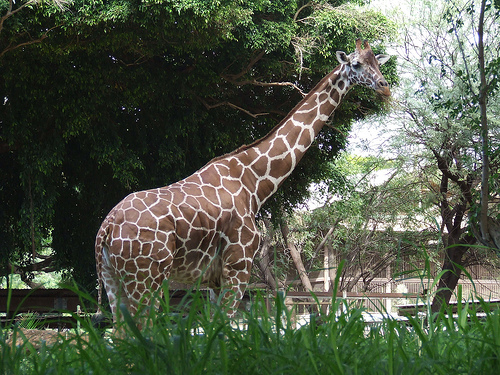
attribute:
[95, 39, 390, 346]
giraffe — tall, standing, brown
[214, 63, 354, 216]
neck — long, very long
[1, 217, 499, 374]
grass — overgrown, green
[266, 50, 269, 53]
leaf — green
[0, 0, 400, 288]
tree — tall, full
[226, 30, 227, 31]
leaf — green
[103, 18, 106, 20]
leaf — green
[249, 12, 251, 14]
leaf — green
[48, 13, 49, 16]
leaf — green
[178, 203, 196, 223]
patch — brown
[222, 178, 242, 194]
patch — brown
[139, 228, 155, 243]
patch — brown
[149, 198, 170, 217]
patch — brown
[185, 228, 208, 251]
patch — brown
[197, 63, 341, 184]
mane — short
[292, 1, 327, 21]
branch — brown, hanging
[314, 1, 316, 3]
leaf — green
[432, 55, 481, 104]
branch — brown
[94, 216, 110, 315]
tail — short, long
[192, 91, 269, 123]
branch — brown, hanging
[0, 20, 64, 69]
branch — brown, hanging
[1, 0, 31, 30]
branch — brown, hanging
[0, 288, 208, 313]
wall — brown, wood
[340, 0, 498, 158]
sky — cloudy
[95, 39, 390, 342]
skin — beautiful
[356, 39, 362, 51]
horn — small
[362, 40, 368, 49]
horn — small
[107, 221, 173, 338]
behind leg — thick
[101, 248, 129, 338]
behind leg — thick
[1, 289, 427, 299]
railing — brown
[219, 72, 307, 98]
branch — hanging